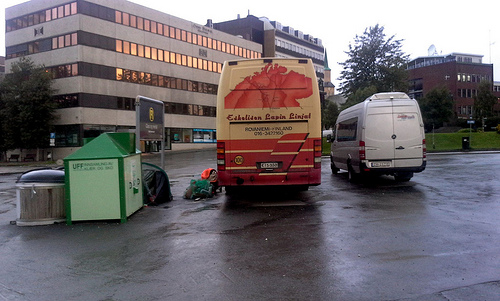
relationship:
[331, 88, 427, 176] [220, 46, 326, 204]
van parked next to bus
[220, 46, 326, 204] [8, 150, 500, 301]
bus parked in parking lot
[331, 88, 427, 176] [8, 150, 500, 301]
van parked in parking lot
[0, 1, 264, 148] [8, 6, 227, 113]
building has windows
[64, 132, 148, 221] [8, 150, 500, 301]
trash bin in parking lot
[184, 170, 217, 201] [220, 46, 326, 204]
bags next to bus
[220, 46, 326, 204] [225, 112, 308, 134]
bus has writing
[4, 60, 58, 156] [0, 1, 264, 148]
tree next to building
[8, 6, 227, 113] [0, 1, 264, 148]
windows on building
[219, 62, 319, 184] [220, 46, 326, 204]
back of bus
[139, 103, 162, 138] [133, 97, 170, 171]
sign on poles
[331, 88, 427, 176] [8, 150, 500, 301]
van in parking lot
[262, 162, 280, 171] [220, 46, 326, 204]
license plate on bus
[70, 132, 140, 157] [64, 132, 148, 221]
top of trash bin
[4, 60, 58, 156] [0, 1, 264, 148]
tree on side of building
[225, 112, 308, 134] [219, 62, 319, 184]
writing on back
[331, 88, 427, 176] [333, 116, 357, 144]
van has windows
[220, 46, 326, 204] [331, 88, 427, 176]
bus next to van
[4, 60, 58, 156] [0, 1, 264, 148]
tree beside building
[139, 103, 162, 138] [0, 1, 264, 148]
sign in front of building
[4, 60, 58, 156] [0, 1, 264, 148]
tree near building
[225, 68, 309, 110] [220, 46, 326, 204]
design on bus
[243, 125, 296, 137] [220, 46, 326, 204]
text on bus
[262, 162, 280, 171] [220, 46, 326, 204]
license plate on a bus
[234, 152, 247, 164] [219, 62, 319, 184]
circle label on back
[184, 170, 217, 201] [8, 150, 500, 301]
bags on parking lot